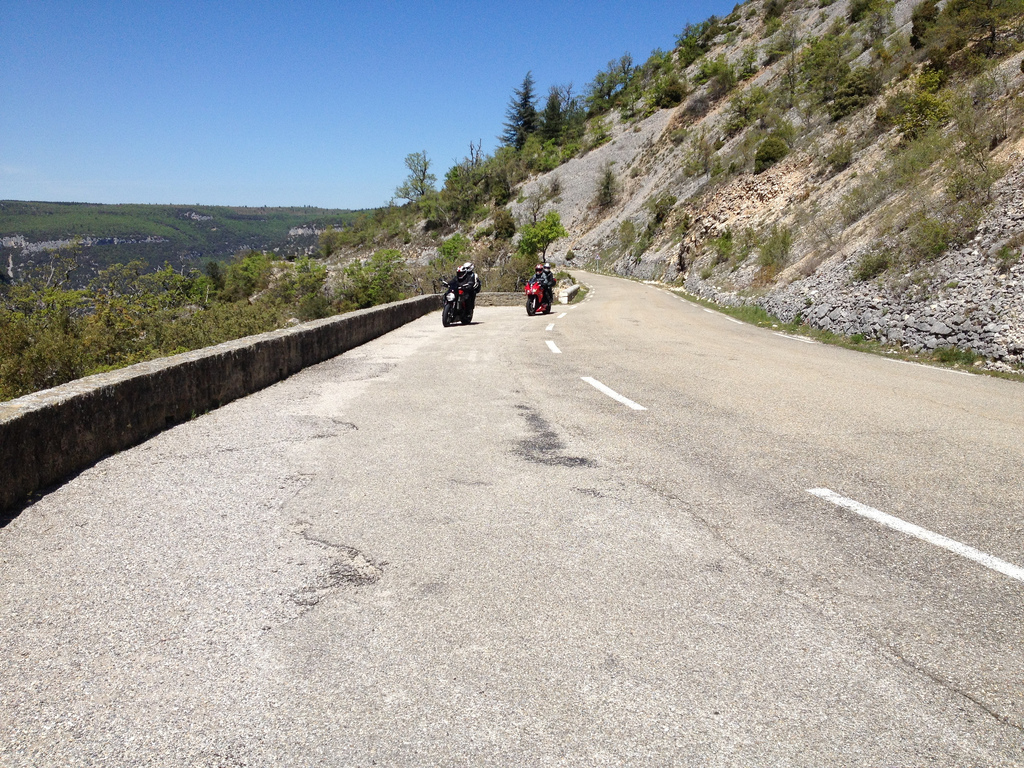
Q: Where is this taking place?
A: On the street.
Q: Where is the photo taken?
A: On the street.